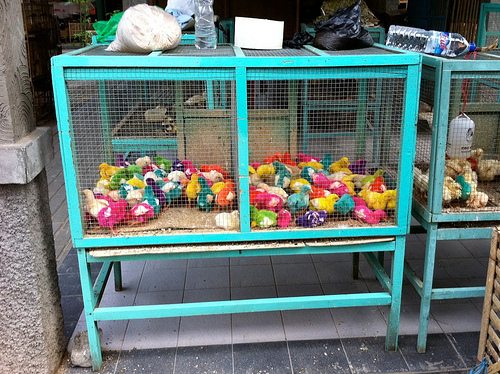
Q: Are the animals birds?
A: Yes, all the animals are birds.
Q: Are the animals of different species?
A: No, all the animals are birds.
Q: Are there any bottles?
A: Yes, there is a bottle.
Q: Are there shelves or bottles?
A: Yes, there is a bottle.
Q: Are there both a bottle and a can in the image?
A: No, there is a bottle but no cans.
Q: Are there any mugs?
A: No, there are no mugs.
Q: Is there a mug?
A: No, there are no mugs.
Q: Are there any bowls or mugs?
A: No, there are no mugs or bowls.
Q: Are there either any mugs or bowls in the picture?
A: No, there are no mugs or bowls.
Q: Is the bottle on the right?
A: Yes, the bottle is on the right of the image.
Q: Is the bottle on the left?
A: No, the bottle is on the right of the image.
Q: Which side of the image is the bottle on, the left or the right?
A: The bottle is on the right of the image.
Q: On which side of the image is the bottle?
A: The bottle is on the right of the image.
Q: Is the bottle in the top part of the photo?
A: Yes, the bottle is in the top of the image.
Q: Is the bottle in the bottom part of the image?
A: No, the bottle is in the top of the image.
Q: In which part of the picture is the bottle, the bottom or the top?
A: The bottle is in the top of the image.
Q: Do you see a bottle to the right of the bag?
A: Yes, there is a bottle to the right of the bag.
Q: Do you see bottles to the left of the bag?
A: No, the bottle is to the right of the bag.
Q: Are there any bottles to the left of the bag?
A: No, the bottle is to the right of the bag.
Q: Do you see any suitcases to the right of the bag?
A: No, there is a bottle to the right of the bag.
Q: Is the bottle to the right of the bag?
A: Yes, the bottle is to the right of the bag.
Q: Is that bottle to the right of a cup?
A: No, the bottle is to the right of the bag.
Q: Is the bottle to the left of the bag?
A: No, the bottle is to the right of the bag.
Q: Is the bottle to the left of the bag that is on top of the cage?
A: No, the bottle is to the right of the bag.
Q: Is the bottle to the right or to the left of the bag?
A: The bottle is to the right of the bag.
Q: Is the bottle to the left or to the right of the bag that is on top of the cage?
A: The bottle is to the right of the bag.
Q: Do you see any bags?
A: Yes, there is a bag.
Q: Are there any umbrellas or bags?
A: Yes, there is a bag.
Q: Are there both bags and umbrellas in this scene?
A: No, there is a bag but no umbrellas.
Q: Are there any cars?
A: No, there are no cars.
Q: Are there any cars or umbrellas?
A: No, there are no cars or umbrellas.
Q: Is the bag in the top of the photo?
A: Yes, the bag is in the top of the image.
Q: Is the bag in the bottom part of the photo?
A: No, the bag is in the top of the image.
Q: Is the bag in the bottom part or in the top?
A: The bag is in the top of the image.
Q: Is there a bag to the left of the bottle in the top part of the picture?
A: Yes, there is a bag to the left of the bottle.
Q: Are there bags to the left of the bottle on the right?
A: Yes, there is a bag to the left of the bottle.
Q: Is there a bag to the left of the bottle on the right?
A: Yes, there is a bag to the left of the bottle.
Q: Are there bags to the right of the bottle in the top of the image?
A: No, the bag is to the left of the bottle.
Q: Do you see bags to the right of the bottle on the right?
A: No, the bag is to the left of the bottle.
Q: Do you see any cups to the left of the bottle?
A: No, there is a bag to the left of the bottle.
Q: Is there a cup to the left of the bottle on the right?
A: No, there is a bag to the left of the bottle.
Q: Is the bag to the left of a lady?
A: No, the bag is to the left of a bottle.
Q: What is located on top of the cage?
A: The bag is on top of the cage.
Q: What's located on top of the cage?
A: The bag is on top of the cage.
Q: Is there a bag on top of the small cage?
A: Yes, there is a bag on top of the cage.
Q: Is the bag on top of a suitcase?
A: No, the bag is on top of a cage.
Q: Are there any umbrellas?
A: No, there are no umbrellas.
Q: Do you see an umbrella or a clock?
A: No, there are no umbrellas or clocks.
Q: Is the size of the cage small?
A: Yes, the cage is small.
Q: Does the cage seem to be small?
A: Yes, the cage is small.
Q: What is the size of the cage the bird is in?
A: The cage is small.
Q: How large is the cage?
A: The cage is small.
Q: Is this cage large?
A: No, the cage is small.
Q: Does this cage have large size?
A: No, the cage is small.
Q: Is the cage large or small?
A: The cage is small.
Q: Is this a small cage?
A: Yes, this is a small cage.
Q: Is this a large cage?
A: No, this is a small cage.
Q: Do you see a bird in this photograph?
A: Yes, there is a bird.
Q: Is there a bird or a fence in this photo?
A: Yes, there is a bird.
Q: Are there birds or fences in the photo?
A: Yes, there is a bird.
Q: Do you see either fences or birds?
A: Yes, there is a bird.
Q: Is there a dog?
A: No, there are no dogs.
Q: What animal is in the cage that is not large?
A: The bird is in the cage.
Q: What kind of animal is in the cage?
A: The animal is a bird.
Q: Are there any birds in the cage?
A: Yes, there is a bird in the cage.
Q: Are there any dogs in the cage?
A: No, there is a bird in the cage.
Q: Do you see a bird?
A: Yes, there is a bird.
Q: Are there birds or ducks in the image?
A: Yes, there is a bird.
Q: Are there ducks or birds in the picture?
A: Yes, there is a bird.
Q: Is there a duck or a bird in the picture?
A: Yes, there is a bird.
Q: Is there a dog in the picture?
A: No, there are no dogs.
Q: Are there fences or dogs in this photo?
A: No, there are no dogs or fences.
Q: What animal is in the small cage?
A: The bird is in the cage.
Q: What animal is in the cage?
A: The bird is in the cage.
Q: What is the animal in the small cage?
A: The animal is a bird.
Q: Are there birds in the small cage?
A: Yes, there is a bird in the cage.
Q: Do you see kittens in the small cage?
A: No, there is a bird in the cage.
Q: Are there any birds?
A: Yes, there is a bird.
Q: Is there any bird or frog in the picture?
A: Yes, there is a bird.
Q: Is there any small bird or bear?
A: Yes, there is a small bird.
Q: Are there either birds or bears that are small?
A: Yes, the bird is small.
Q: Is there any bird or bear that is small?
A: Yes, the bird is small.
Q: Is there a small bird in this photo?
A: Yes, there is a small bird.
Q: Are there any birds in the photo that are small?
A: Yes, there is a bird that is small.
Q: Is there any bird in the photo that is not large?
A: Yes, there is a small bird.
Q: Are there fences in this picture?
A: No, there are no fences.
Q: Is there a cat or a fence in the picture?
A: No, there are no fences or cats.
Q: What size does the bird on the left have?
A: The bird has small size.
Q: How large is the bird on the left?
A: The bird is small.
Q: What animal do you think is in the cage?
A: The animal is a bird.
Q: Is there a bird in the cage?
A: Yes, there is a bird in the cage.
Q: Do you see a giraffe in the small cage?
A: No, there is a bird in the cage.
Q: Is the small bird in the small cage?
A: Yes, the bird is in the cage.